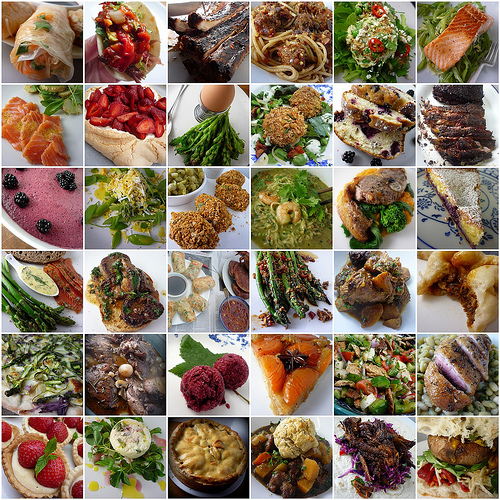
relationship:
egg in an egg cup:
[200, 87, 229, 109] [193, 99, 213, 123]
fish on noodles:
[422, 3, 494, 70] [418, 1, 491, 83]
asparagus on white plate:
[253, 250, 322, 326] [251, 252, 336, 331]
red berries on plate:
[179, 353, 248, 413] [168, 342, 248, 412]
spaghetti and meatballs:
[253, 6, 332, 78] [258, 12, 333, 57]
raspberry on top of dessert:
[11, 191, 32, 212] [14, 193, 69, 243]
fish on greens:
[422, 3, 494, 70] [412, 1, 494, 85]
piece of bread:
[439, 83, 469, 195] [15, 250, 63, 262]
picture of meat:
[6, 2, 498, 498] [172, 2, 244, 79]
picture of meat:
[6, 2, 498, 498] [420, 87, 491, 165]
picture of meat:
[6, 2, 498, 498] [419, 334, 494, 412]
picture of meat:
[6, 2, 498, 498] [337, 419, 414, 499]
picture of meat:
[6, 2, 498, 498] [337, 167, 414, 241]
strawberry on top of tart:
[20, 440, 66, 486] [0, 460, 19, 495]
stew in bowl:
[253, 420, 334, 496] [254, 420, 334, 497]